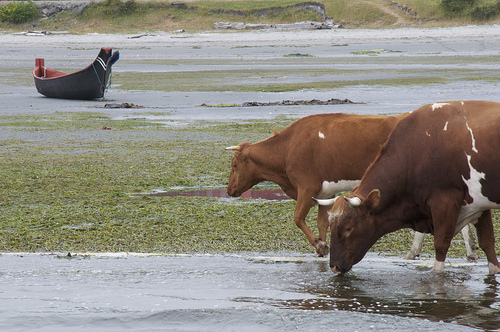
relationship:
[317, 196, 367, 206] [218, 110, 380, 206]
horns on cow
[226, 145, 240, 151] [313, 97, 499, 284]
horn on cow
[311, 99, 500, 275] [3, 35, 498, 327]
cow drinking water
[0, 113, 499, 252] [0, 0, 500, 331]
grass on ground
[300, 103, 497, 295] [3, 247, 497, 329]
cow on water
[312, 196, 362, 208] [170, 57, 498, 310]
horns on cow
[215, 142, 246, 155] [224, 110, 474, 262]
horn on cow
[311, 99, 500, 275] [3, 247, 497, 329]
cow drinking water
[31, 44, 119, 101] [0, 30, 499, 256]
boat on ground